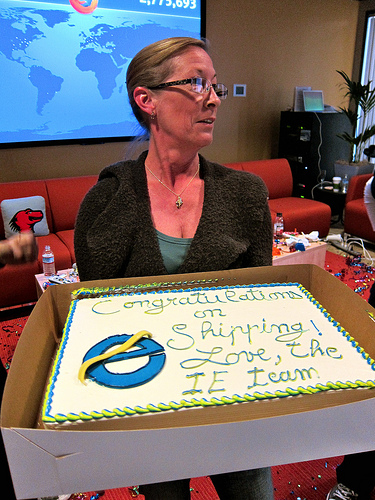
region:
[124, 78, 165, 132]
the lady has a really red ear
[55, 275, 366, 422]
she is holding a cake box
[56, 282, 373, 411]
the cake is says congratulations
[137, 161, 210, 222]
the lady is wearing a gold necklace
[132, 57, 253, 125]
the lady is wearing glasses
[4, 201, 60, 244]
their is a red animal on the white pillow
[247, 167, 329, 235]
the couch is red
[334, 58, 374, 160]
this is a house tree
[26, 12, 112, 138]
there is a map of the world in the background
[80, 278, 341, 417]
the cake is white, blue, and yellow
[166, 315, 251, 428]
a cake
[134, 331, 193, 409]
a cake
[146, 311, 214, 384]
a cake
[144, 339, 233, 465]
a cake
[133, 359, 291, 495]
a cake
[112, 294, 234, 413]
a cake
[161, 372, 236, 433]
a cake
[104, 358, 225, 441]
a cake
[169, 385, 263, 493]
a cake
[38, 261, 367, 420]
Large white sheet cake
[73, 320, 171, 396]
Blue and yellow letter e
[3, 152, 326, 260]
The couch is long and red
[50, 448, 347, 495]
There is confetti on the floor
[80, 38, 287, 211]
The woman is wearing glasses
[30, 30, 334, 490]
The woman is holding a box with cake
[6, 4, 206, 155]
Large screen with a map of the continents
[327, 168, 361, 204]
White coffee cup on black cabinet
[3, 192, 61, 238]
White pillow with an image of a dinosaur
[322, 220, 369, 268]
Many white wires plugged in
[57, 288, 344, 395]
the cake is blue and yellow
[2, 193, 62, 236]
the pillow has a red and black character on it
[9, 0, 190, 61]
the picture is blue white and red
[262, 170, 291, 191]
the couch is orangeish red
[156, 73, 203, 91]
the frame of the glasses are black with gold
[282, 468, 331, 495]
the carpet is red with confetti on it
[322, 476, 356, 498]
the shoe is grey and white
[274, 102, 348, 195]
the filing cabinet is black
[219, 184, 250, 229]
the sweater is blackish grey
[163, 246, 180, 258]
the shirt is teal in color